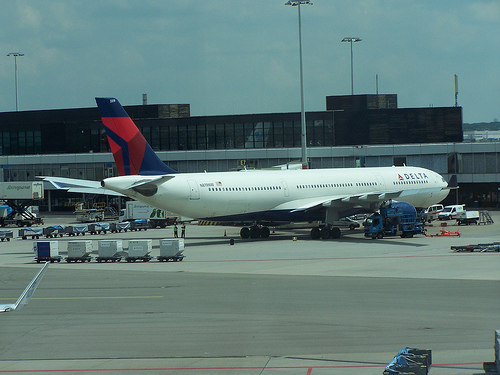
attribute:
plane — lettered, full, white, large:
[36, 95, 462, 239]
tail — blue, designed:
[35, 96, 179, 215]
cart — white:
[156, 238, 188, 262]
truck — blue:
[361, 201, 428, 240]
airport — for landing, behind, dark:
[0, 93, 498, 215]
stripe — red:
[2, 360, 494, 374]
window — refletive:
[323, 116, 337, 147]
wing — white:
[276, 175, 463, 213]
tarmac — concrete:
[2, 210, 497, 371]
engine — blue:
[323, 196, 395, 218]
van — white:
[438, 202, 467, 221]